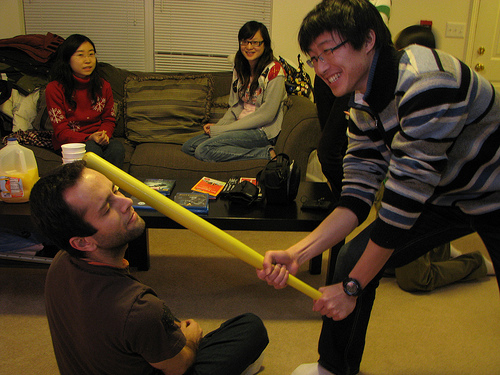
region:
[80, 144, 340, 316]
a yellow bat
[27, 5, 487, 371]
man hitting other man with bat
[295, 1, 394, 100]
a man who wears glasses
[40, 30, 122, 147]
woman in red sweater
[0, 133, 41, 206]
a gallon of orange juice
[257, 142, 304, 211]
black bag on table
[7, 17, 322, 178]
two woman sitting on couch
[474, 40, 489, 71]
gold door lock and knob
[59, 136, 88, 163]
top part of a stack of cups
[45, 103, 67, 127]
a white snow flake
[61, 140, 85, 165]
White Styrofoam Cups on table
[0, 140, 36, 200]
a plastic jug of orange juice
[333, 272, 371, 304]
man with watch on wrist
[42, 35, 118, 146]
woman wearing Christmas sweater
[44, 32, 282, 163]
two women sitting on a couch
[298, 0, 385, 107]
a man wearing glasses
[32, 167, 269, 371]
a man sitting on floor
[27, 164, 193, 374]
a man wearing a brown shirt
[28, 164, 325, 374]
man being hit with a yellow stick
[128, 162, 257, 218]
several books scattered on a coffee table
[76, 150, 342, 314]
A yellow plastic bat.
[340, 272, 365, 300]
A black wrist watch.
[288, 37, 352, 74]
A pair of black framed glasses.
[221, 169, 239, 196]
A black remote controller.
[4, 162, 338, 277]
A black coffee table.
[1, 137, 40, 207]
A clear jug with a blue lid.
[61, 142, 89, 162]
A stack of white cups.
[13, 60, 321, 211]
A dark colored couch.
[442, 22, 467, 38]
A white light switch panel.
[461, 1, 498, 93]
A white door.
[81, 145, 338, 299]
yellow baseball bat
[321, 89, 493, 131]
grey, blue and black shirt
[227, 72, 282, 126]
grey and red sweater on woman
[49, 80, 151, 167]
red and white sweater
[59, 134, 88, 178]
white cups on table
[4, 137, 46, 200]
orange juice in carton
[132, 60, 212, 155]
green and brown pillow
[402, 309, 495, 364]
tan colored carpet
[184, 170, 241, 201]
red white and black manual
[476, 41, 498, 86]
gold knobs on door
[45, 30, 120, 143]
Woman in red sweater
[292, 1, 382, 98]
Man with smile on his face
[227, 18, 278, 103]
Woman with black hair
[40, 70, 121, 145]
Red sweater with white snowflakes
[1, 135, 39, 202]
Plastic jug of orange juice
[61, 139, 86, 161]
Stack of white cups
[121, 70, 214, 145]
Brown pillow with dark brown stripes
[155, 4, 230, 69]
White blinds on window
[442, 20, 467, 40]
White switch plate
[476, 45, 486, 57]
Gold lock on door